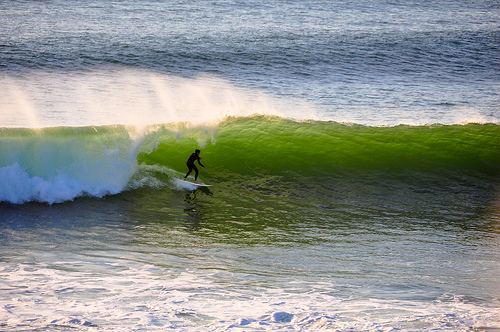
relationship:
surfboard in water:
[178, 171, 213, 188] [4, 3, 484, 330]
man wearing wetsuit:
[182, 149, 206, 185] [176, 151, 208, 183]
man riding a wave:
[182, 149, 206, 185] [8, 124, 278, 162]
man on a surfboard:
[182, 149, 206, 185] [178, 175, 213, 187]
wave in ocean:
[1, 110, 494, 214] [0, 4, 497, 330]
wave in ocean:
[46, 55, 188, 225] [318, 159, 424, 238]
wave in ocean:
[0, 27, 499, 80] [0, 4, 497, 330]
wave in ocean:
[329, 26, 399, 116] [365, 4, 437, 48]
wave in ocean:
[387, 301, 442, 326] [0, 4, 497, 330]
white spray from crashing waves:
[1, 75, 315, 125] [3, 115, 496, 205]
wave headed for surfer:
[1, 110, 494, 214] [183, 148, 205, 178]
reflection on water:
[174, 193, 214, 229] [4, 3, 484, 330]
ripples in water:
[18, 284, 78, 316] [4, 3, 484, 330]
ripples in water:
[93, 291, 313, 329] [4, 3, 484, 330]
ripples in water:
[12, 262, 497, 329] [4, 3, 484, 330]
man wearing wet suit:
[182, 149, 206, 185] [183, 153, 206, 179]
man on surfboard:
[173, 139, 215, 189] [171, 173, 212, 194]